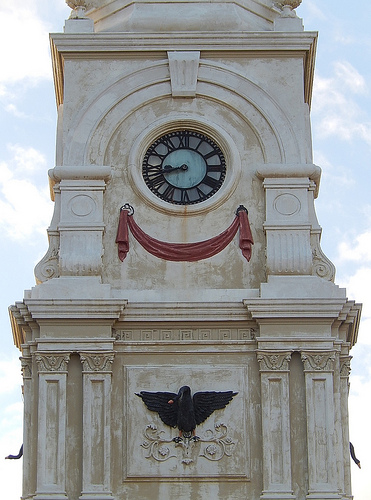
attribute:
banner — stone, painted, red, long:
[114, 203, 256, 264]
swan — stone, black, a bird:
[133, 382, 241, 438]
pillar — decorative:
[241, 288, 350, 499]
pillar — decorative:
[19, 295, 132, 500]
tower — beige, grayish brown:
[8, 1, 363, 499]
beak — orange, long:
[165, 396, 175, 406]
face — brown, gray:
[143, 132, 227, 204]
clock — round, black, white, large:
[125, 111, 243, 215]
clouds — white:
[2, 141, 56, 240]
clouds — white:
[0, 4, 56, 87]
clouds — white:
[330, 228, 370, 301]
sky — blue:
[1, 1, 367, 319]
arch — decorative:
[60, 56, 310, 170]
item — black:
[6, 439, 27, 465]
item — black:
[347, 440, 360, 469]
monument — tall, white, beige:
[8, 0, 363, 499]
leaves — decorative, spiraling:
[136, 421, 236, 465]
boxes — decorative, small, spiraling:
[115, 324, 255, 343]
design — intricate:
[34, 349, 116, 372]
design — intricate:
[254, 346, 337, 372]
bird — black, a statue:
[134, 384, 238, 437]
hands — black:
[149, 160, 192, 180]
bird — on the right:
[347, 438, 361, 471]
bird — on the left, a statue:
[5, 438, 24, 463]